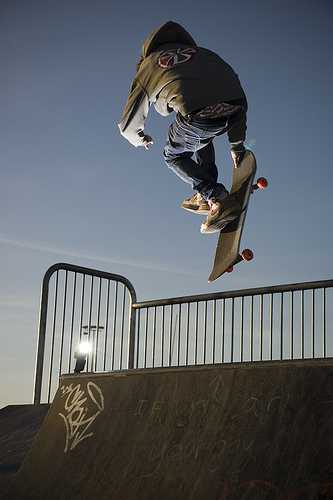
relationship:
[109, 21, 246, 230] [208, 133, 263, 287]
man on a skateboard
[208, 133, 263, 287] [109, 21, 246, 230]
skateboard under man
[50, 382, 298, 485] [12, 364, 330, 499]
graffiti on ramp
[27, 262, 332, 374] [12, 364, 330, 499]
fence above ramp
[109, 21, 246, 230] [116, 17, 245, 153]
man wearing a hoodie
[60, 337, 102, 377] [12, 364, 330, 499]
light on ramp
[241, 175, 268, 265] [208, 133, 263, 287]
wheels on skateboard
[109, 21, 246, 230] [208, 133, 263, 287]
man riding skateboard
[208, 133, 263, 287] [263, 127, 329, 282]
skateboard in air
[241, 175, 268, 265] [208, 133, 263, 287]
wheels are on skateboard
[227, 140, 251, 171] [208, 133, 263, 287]
hand holding skateboard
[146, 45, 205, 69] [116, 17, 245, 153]
graphic on hoodie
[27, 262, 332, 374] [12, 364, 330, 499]
fence over ramp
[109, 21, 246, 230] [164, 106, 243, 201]
man wearing jeans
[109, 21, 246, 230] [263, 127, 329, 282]
man in air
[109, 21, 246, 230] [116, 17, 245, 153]
man wearing hoodie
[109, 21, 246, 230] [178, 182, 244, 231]
man wearing shoes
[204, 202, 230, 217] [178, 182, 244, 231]
nike logo on shoes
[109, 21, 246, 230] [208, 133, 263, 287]
man over skateboard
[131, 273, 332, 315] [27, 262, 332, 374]
pole on fence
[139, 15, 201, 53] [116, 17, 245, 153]
hood on hoodie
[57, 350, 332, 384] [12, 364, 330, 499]
top of ramp